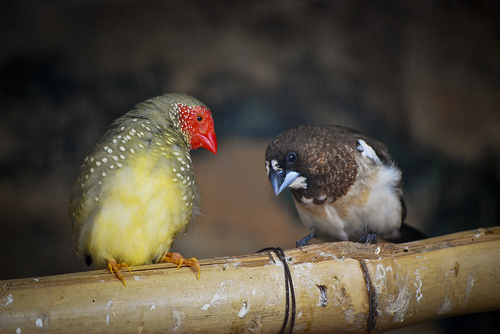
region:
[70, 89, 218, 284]
the bird has red color beak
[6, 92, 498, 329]
two birds are standing on the same wood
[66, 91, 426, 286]
the bird with brown feet is looking at the other bird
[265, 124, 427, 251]
the bird has black tarsus and feet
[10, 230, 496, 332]
a thin black thread is tied around the wood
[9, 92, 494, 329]
a thin rope is tied around the wood between the two birds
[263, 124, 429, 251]
the beak of the bird is sharp and pointing downwards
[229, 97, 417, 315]
a bird on a pole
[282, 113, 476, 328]
a small bird on a pole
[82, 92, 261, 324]
a small bird on pole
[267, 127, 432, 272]
a small bird outside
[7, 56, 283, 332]
a small bird outside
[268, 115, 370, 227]
a small bird standing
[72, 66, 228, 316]
a small bird standing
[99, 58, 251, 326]
a small bird outside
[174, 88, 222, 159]
the beak is red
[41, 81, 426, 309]
two birds on a log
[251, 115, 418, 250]
the bird is brown and white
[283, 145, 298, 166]
the eye is black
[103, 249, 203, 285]
the legs of bird are yellow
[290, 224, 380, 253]
the legs of bird are blue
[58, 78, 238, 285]
bird is turned to the left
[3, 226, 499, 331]
the pole is color brown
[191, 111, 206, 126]
the eye is color black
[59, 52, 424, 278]
a pair of birds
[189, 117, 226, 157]
red beak on the birds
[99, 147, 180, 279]
yellow feathers on the bird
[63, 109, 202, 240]
white spots on bird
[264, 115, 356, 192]
brown feathers on bird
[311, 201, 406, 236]
white feathers on bird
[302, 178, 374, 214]
tan feathers on bird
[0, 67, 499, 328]
birds sitting on bamboo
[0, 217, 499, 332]
the bamboo is brown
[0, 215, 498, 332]
white spots on bamboo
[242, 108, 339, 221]
head of a bird